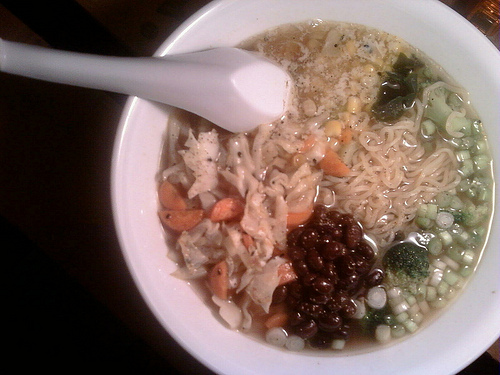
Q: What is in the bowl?
A: Soup.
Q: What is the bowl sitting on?
A: The table.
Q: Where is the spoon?
A: In the bowl.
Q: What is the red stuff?
A: Beans.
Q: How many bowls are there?
A: One.